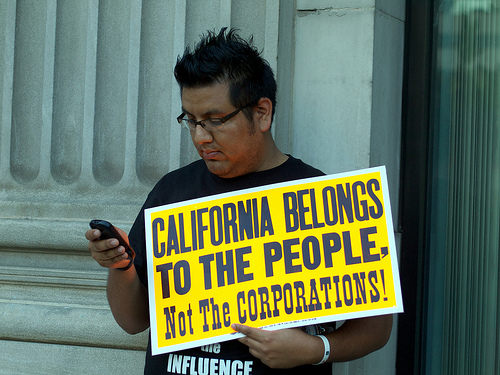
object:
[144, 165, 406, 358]
sign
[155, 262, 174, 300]
letter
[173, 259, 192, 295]
letter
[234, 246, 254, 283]
letter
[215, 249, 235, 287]
letter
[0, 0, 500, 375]
facade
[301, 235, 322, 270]
letter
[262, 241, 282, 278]
letter